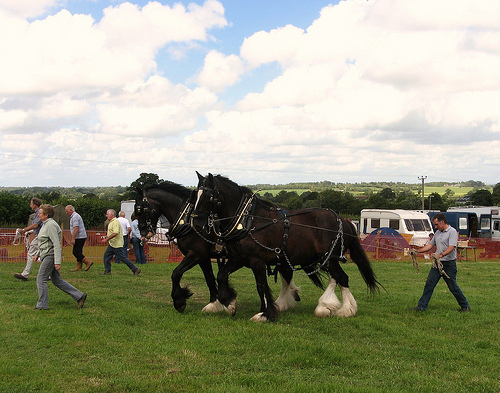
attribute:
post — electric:
[416, 171, 430, 213]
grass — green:
[162, 327, 427, 391]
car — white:
[365, 200, 492, 278]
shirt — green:
[34, 217, 64, 264]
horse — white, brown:
[187, 170, 388, 322]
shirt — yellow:
[103, 217, 125, 249]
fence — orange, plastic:
[18, 210, 479, 260]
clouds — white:
[22, 17, 488, 135]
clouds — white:
[0, 0, 498, 187]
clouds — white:
[1, 37, 484, 168]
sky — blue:
[229, 1, 316, 21]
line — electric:
[1, 153, 431, 183]